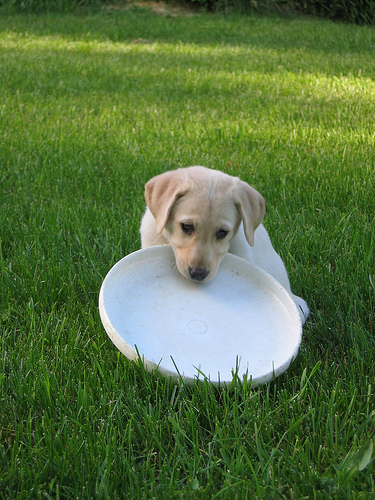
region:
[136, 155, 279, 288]
head of a dog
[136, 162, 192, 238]
ear of a dog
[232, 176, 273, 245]
ear of a dog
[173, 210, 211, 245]
eye of a dog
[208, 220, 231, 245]
eye of a dog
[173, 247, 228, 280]
nose of a dog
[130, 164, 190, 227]
an ear of a dog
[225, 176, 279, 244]
an ear of a dog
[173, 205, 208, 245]
an eye of a dog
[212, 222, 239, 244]
an eye of a dog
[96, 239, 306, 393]
Dog holding a frisbee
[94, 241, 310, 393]
Dog is holding a frisbee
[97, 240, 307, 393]
Dog holding a white frisbee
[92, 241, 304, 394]
Dog is holding a white frisbee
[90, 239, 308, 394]
Dog holding a frisbee in its mouth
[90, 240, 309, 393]
Dog is holding a frisbee in its mouth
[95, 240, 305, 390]
Dog holding a white frisbee in its mouth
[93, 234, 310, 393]
Dog is holding a white frisbee in its mouth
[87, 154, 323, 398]
Dog is on the grass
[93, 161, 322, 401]
Puppy is on the grass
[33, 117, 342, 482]
A dog is sitting in the grass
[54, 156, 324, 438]
A dog is playing with his master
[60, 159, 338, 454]
A dog is holding a frisbee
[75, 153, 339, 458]
A dog is in a city park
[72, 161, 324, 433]
A dog has a frisbee in his mouth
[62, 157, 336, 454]
A dog is looking for attention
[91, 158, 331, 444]
A dog is wanting to play catch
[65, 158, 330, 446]
The dog is a very young puppy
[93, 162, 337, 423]
The dog is out in the daytime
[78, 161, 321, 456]
The dog is enjoying the day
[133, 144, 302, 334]
white dog has frisbee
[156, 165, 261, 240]
dog has brown ears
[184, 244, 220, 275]
dog has black nose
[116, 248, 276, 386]
frisbee in dog's mouth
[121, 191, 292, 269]
dog has white body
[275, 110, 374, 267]
green grass around dog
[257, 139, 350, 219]
green grass is thick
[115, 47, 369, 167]
light shines on grass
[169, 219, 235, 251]
dog has dark eyes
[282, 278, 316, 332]
dog has white paws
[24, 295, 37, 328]
blade of green grass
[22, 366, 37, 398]
blade of green grass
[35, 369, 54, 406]
blade of green grass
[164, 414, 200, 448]
blade of green grass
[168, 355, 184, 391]
blade of green grass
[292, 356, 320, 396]
blade of green grass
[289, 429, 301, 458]
blade of green grass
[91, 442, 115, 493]
blade of green grass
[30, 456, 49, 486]
blade of green grass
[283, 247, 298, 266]
blade of green grass